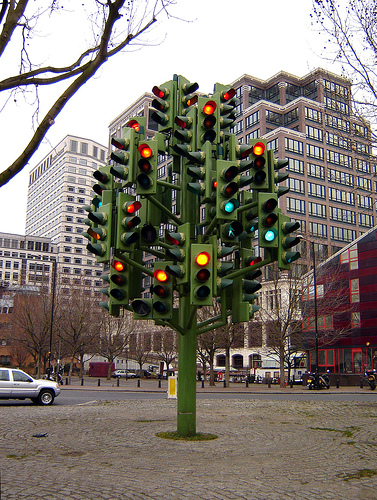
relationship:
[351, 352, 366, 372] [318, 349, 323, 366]
door with window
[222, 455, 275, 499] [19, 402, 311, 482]
bricks on ground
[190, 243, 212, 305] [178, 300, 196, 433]
traffic light on pole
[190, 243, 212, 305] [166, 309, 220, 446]
traffic light on pole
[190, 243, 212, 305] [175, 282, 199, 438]
traffic light on pole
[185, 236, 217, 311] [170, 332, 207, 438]
traffic light on pole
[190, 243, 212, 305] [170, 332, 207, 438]
traffic light on pole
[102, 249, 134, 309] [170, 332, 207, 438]
traffic light on pole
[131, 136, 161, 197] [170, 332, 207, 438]
traffic light on pole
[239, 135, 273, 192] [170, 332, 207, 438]
traffic light on pole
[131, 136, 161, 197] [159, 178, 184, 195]
traffic light on pole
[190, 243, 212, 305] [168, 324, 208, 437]
traffic light on pole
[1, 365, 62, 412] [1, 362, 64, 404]
car on street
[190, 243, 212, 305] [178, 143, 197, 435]
traffic light on pole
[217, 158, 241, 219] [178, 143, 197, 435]
traffic light on pole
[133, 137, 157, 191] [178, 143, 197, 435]
traffic light on pole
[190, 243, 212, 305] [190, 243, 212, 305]
traffic light on traffic light